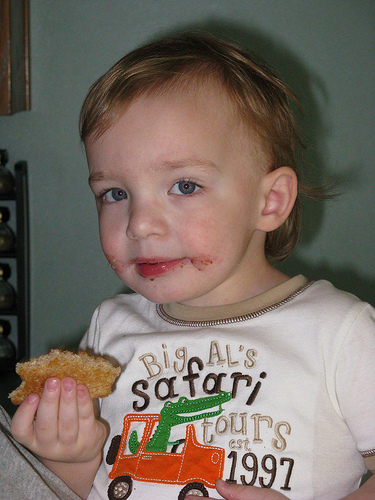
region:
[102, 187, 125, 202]
the blue eye of the face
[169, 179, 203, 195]
the blue eye of the face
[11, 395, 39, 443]
the finger of the hand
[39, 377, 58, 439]
the finger of the hand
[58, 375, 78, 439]
the finger of the hand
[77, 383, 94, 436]
the finger of the hand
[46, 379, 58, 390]
the fingernail on the finger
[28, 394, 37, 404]
the fingernail on the finger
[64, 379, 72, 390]
the fingernail on the finger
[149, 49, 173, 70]
boy has blonde hair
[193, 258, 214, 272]
jelly on side mouth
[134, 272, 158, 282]
jelly under boy lip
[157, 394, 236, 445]
alligator in orange car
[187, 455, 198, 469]
orange car on shirt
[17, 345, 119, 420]
toast in boys hand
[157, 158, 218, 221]
right eye of boy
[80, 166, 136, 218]
left eye of boy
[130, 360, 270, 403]
word safari on shirt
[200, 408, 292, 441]
word tours on shirt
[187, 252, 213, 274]
mess on a toddler's face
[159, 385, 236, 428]
face of an alligator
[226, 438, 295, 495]
date on a t shirt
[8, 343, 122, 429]
toast in a hand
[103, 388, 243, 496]
alligator in a truck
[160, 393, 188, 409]
eyes on an alligator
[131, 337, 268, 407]
writing on a shirt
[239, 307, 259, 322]
stitching on a neckline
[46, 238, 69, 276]
grey painted wall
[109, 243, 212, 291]
messy face on a toddler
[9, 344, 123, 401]
A piece of toast in a child's hand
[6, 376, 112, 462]
The right hand of a boy holding toast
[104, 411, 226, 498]
A red truck on a shirt driven by a crocodile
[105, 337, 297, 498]
The logo of a toddler's shirt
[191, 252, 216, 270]
Some food on a childs face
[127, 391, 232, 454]
A crocodile driving a red truck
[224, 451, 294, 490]
The date 1997 on a shirt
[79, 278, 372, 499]
A white shirt worn by a child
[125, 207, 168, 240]
A child's nose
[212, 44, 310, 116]
The red cowlick of a child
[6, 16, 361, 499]
HUNGRY CHILD EATING JELLY BREAD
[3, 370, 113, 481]
HAND OF HUNGRY CHILD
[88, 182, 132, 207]
EYE OF HUNGRY CHILD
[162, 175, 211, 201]
EYE OF HUNGRY CHILD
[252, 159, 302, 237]
EAR OF HUNGRY CHILD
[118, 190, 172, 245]
NOSE OF HUNGRY CHILD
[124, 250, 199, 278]
MOUTH OF HUNGRY CHILD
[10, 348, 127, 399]
SANDWICH OF HUNGRY CHILD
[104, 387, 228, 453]
ALLIGATOR ON CHILD'S SHIRT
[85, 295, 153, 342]
SHOULDER OF HUNGRY CHILD